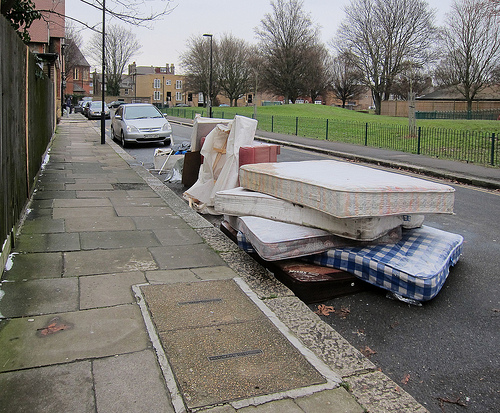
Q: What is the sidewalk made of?
A: Stone tiles.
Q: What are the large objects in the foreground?
A: Mattresses.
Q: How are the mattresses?
A: Old and dirty.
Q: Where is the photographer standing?
A: On the sidewalk.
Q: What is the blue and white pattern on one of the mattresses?
A: Gingham.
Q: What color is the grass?
A: Green.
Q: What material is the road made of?
A: Asphalt.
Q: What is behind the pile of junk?
A: A car.